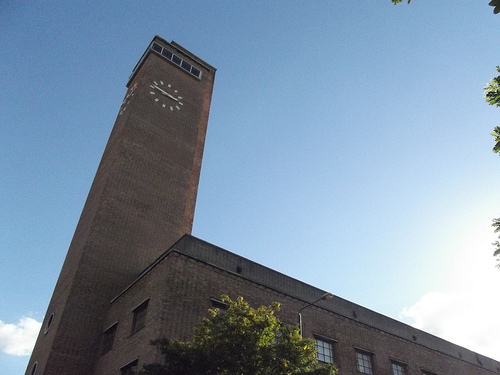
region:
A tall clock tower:
[79, 25, 248, 240]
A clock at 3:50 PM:
[147, 73, 189, 118]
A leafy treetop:
[158, 293, 335, 373]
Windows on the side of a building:
[92, 311, 156, 368]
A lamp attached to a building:
[314, 283, 339, 308]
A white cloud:
[3, 293, 52, 365]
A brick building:
[118, 232, 489, 374]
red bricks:
[129, 153, 176, 216]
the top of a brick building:
[331, 276, 481, 369]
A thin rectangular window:
[146, 34, 213, 81]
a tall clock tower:
[88, 11, 262, 142]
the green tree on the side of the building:
[114, 277, 357, 373]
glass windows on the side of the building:
[290, 313, 353, 370]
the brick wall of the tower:
[124, 143, 188, 220]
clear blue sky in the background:
[271, 59, 416, 174]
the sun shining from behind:
[410, 185, 498, 285]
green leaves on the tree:
[166, 291, 305, 371]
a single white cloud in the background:
[10, 296, 40, 359]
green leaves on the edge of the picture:
[450, 11, 498, 281]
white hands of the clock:
[146, 70, 194, 125]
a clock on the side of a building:
[137, 76, 194, 117]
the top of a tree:
[146, 271, 336, 373]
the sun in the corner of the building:
[376, 171, 498, 351]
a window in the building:
[299, 330, 350, 371]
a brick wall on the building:
[165, 274, 193, 318]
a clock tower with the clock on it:
[28, 31, 241, 366]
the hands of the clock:
[152, 81, 187, 104]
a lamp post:
[285, 284, 349, 357]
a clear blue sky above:
[270, 48, 444, 246]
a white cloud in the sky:
[0, 293, 53, 360]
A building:
[307, 300, 401, 371]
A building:
[338, 315, 376, 366]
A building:
[365, 331, 405, 373]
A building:
[351, 318, 409, 370]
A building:
[360, 268, 422, 369]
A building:
[371, 326, 395, 366]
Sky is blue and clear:
[246, 50, 422, 156]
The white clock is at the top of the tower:
[135, 65, 196, 115]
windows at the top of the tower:
[135, 31, 241, 88]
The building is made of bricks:
[108, 235, 426, 372]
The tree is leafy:
[151, 299, 332, 372]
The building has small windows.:
[106, 233, 409, 372]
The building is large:
[33, 23, 481, 374]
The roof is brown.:
[104, 228, 492, 368]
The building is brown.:
[39, 168, 401, 373]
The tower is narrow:
[105, 25, 218, 365]